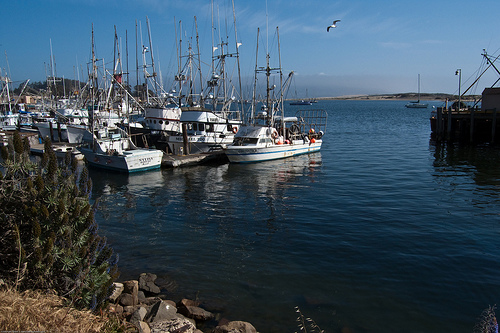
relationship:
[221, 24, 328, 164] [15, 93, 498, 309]
boat in harbor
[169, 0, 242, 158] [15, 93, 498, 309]
boat in harbor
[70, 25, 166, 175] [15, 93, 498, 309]
boat in harbor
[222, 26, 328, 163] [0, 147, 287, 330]
boat near shore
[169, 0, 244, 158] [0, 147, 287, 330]
boat near shore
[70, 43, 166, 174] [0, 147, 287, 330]
boat near shore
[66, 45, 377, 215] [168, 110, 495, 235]
boats near water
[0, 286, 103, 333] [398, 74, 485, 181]
grass growing near shore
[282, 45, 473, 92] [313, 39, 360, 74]
sky has clouds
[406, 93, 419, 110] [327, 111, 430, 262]
boats in water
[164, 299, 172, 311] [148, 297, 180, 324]
line on rock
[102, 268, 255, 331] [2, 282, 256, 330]
rocks on shore line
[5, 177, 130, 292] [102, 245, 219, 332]
bushes on shore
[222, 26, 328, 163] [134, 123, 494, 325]
boat in harbor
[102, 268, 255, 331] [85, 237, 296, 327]
rocks by shore line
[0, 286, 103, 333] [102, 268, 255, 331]
grass by rocks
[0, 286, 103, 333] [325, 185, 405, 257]
grass next to water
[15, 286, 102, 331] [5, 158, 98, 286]
grass in front of shrub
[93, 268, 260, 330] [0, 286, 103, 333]
pile on right of grass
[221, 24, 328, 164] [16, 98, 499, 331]
boat floating in water water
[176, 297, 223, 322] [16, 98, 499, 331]
gray rock in water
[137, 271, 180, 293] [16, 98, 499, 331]
gray rock in water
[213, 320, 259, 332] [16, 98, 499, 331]
gray rock in water